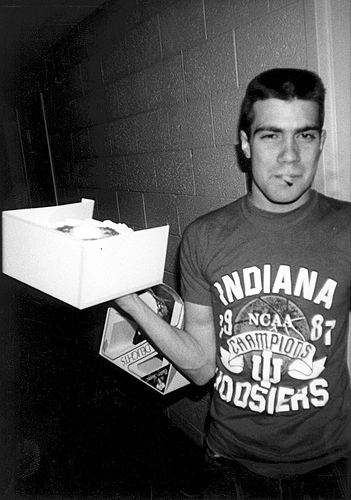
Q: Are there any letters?
A: Yes, there are letters.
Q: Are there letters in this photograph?
A: Yes, there are letters.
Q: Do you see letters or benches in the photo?
A: Yes, there are letters.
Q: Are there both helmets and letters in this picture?
A: No, there are letters but no helmets.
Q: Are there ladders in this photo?
A: No, there are no ladders.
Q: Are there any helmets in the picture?
A: No, there are no helmets.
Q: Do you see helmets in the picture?
A: No, there are no helmets.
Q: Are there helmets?
A: No, there are no helmets.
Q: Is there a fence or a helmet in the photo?
A: No, there are no helmets or fences.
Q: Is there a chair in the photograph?
A: No, there are no chairs.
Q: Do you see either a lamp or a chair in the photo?
A: No, there are no chairs or lamps.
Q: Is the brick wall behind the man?
A: Yes, the wall is behind the man.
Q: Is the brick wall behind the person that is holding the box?
A: Yes, the wall is behind the man.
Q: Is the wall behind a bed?
A: No, the wall is behind the man.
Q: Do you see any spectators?
A: No, there are no spectators.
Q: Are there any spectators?
A: No, there are no spectators.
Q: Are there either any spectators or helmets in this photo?
A: No, there are no spectators or helmets.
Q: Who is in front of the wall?
A: The man is in front of the wall.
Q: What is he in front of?
A: The man is in front of the wall.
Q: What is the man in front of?
A: The man is in front of the wall.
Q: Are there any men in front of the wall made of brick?
A: Yes, there is a man in front of the wall.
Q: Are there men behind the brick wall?
A: No, the man is in front of the wall.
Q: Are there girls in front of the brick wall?
A: No, there is a man in front of the wall.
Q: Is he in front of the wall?
A: Yes, the man is in front of the wall.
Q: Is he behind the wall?
A: No, the man is in front of the wall.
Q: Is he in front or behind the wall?
A: The man is in front of the wall.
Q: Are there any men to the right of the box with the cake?
A: Yes, there is a man to the right of the box.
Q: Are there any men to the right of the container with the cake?
A: Yes, there is a man to the right of the box.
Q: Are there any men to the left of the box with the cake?
A: No, the man is to the right of the box.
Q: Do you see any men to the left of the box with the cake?
A: No, the man is to the right of the box.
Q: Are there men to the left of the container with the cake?
A: No, the man is to the right of the box.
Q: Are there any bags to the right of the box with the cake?
A: No, there is a man to the right of the box.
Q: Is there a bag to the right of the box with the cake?
A: No, there is a man to the right of the box.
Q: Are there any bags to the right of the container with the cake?
A: No, there is a man to the right of the box.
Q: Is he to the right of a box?
A: Yes, the man is to the right of a box.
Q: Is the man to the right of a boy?
A: No, the man is to the right of a box.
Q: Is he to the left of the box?
A: No, the man is to the right of the box.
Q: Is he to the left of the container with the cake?
A: No, the man is to the right of the box.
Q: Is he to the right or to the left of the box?
A: The man is to the right of the box.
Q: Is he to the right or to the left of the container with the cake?
A: The man is to the right of the box.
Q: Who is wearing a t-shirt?
A: The man is wearing a t-shirt.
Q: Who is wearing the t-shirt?
A: The man is wearing a t-shirt.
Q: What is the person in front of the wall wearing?
A: The man is wearing a tshirt.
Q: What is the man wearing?
A: The man is wearing a tshirt.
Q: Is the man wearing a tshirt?
A: Yes, the man is wearing a tshirt.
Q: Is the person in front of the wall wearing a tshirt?
A: Yes, the man is wearing a tshirt.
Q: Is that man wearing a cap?
A: No, the man is wearing a tshirt.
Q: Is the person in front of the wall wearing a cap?
A: No, the man is wearing a tshirt.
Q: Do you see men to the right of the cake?
A: Yes, there is a man to the right of the cake.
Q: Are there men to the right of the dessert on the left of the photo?
A: Yes, there is a man to the right of the cake.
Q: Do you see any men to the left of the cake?
A: No, the man is to the right of the cake.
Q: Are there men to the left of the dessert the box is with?
A: No, the man is to the right of the cake.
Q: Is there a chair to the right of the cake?
A: No, there is a man to the right of the cake.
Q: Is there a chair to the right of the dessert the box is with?
A: No, there is a man to the right of the cake.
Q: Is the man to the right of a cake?
A: Yes, the man is to the right of a cake.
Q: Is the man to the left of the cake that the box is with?
A: No, the man is to the right of the cake.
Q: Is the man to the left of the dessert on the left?
A: No, the man is to the right of the cake.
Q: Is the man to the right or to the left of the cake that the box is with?
A: The man is to the right of the cake.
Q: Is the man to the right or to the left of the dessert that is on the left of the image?
A: The man is to the right of the cake.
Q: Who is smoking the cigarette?
A: The man is smoking the cigarette.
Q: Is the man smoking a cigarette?
A: Yes, the man is smoking a cigarette.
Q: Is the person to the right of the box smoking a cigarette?
A: Yes, the man is smoking a cigarette.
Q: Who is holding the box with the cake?
A: The man is holding the box.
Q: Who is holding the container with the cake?
A: The man is holding the box.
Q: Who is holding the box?
A: The man is holding the box.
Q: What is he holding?
A: The man is holding the box.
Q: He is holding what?
A: The man is holding the box.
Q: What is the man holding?
A: The man is holding the box.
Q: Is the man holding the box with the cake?
A: Yes, the man is holding the box.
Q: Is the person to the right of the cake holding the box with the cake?
A: Yes, the man is holding the box.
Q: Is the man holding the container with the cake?
A: Yes, the man is holding the box.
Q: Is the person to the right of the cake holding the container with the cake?
A: Yes, the man is holding the box.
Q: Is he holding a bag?
A: No, the man is holding the box.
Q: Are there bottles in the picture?
A: No, there are no bottles.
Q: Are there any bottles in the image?
A: No, there are no bottles.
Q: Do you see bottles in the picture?
A: No, there are no bottles.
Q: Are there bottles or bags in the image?
A: No, there are no bottles or bags.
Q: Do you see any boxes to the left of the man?
A: Yes, there is a box to the left of the man.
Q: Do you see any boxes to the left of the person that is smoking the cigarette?
A: Yes, there is a box to the left of the man.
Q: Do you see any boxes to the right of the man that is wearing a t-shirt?
A: No, the box is to the left of the man.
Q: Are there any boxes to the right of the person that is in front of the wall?
A: No, the box is to the left of the man.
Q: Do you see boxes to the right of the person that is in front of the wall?
A: No, the box is to the left of the man.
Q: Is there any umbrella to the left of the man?
A: No, there is a box to the left of the man.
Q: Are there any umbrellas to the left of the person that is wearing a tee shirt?
A: No, there is a box to the left of the man.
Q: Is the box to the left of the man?
A: Yes, the box is to the left of the man.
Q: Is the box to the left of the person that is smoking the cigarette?
A: Yes, the box is to the left of the man.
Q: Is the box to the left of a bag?
A: No, the box is to the left of the man.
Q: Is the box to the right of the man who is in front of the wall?
A: No, the box is to the left of the man.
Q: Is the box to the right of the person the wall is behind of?
A: No, the box is to the left of the man.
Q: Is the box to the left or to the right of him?
A: The box is to the left of the man.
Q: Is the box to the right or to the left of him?
A: The box is to the left of the man.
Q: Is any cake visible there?
A: Yes, there is a cake.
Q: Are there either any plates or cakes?
A: Yes, there is a cake.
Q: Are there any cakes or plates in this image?
A: Yes, there is a cake.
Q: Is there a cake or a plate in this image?
A: Yes, there is a cake.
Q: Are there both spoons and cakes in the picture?
A: No, there is a cake but no spoons.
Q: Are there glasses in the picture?
A: No, there are no glasses.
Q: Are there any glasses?
A: No, there are no glasses.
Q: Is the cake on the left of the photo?
A: Yes, the cake is on the left of the image.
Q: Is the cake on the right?
A: No, the cake is on the left of the image.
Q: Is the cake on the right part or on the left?
A: The cake is on the left of the image.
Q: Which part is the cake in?
A: The cake is on the left of the image.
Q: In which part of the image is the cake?
A: The cake is on the left of the image.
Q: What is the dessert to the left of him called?
A: The dessert is a cake.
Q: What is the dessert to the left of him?
A: The dessert is a cake.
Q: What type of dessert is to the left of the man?
A: The dessert is a cake.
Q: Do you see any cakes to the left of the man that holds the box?
A: Yes, there is a cake to the left of the man.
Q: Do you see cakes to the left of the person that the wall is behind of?
A: Yes, there is a cake to the left of the man.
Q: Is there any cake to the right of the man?
A: No, the cake is to the left of the man.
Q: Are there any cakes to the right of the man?
A: No, the cake is to the left of the man.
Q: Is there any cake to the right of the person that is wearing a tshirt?
A: No, the cake is to the left of the man.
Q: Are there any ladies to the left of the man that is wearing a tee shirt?
A: No, there is a cake to the left of the man.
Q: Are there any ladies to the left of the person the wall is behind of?
A: No, there is a cake to the left of the man.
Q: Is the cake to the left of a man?
A: Yes, the cake is to the left of a man.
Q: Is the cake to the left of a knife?
A: No, the cake is to the left of a man.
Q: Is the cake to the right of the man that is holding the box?
A: No, the cake is to the left of the man.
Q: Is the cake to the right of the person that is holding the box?
A: No, the cake is to the left of the man.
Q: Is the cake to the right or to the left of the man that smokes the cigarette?
A: The cake is to the left of the man.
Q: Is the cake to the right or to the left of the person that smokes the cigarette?
A: The cake is to the left of the man.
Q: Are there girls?
A: No, there are no girls.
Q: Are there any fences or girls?
A: No, there are no girls or fences.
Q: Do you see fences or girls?
A: No, there are no girls or fences.